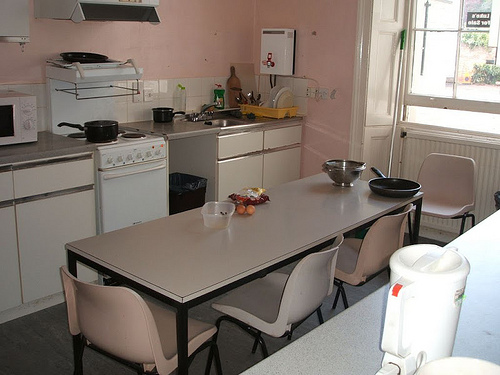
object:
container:
[200, 196, 237, 228]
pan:
[366, 161, 421, 198]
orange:
[245, 199, 256, 220]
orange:
[236, 210, 245, 218]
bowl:
[320, 155, 368, 187]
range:
[46, 56, 169, 287]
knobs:
[115, 153, 125, 162]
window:
[400, 4, 483, 135]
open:
[403, 108, 481, 128]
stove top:
[68, 120, 165, 149]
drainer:
[238, 101, 300, 118]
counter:
[4, 128, 98, 165]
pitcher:
[379, 239, 471, 373]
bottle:
[210, 80, 226, 113]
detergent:
[214, 96, 221, 106]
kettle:
[375, 240, 470, 369]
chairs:
[55, 265, 216, 354]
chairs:
[215, 229, 346, 358]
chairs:
[335, 196, 418, 293]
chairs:
[408, 150, 479, 231]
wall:
[255, 10, 485, 243]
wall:
[9, 6, 256, 316]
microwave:
[6, 88, 39, 148]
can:
[170, 167, 207, 214]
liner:
[172, 171, 205, 205]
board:
[223, 61, 242, 107]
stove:
[41, 59, 171, 259]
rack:
[237, 102, 300, 118]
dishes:
[253, 86, 292, 105]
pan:
[55, 117, 119, 145]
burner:
[81, 136, 118, 146]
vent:
[32, 3, 161, 27]